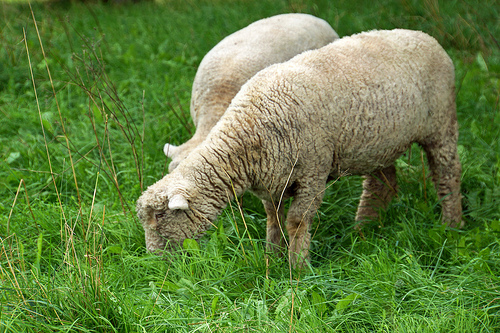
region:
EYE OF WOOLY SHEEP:
[154, 210, 167, 224]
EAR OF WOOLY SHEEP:
[166, 194, 190, 217]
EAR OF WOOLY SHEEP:
[157, 138, 177, 157]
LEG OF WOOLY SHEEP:
[262, 188, 287, 273]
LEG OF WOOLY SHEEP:
[286, 190, 308, 278]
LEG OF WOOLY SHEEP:
[353, 173, 395, 250]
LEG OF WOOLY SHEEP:
[419, 135, 469, 252]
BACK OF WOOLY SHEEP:
[311, 50, 385, 79]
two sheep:
[129, 14, 454, 261]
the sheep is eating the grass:
[141, 232, 168, 261]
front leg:
[279, 222, 315, 277]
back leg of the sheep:
[441, 182, 470, 224]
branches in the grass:
[70, 62, 139, 142]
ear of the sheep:
[168, 197, 188, 214]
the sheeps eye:
[153, 209, 167, 224]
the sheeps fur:
[274, 85, 411, 141]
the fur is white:
[275, 70, 425, 127]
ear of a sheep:
[166, 197, 191, 212]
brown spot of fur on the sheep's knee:
[284, 214, 313, 234]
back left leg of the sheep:
[416, 138, 478, 225]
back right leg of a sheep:
[356, 165, 405, 228]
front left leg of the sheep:
[283, 172, 337, 271]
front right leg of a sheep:
[261, 190, 287, 253]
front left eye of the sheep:
[153, 209, 165, 221]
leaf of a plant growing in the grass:
[183, 238, 200, 257]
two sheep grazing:
[130, 8, 471, 275]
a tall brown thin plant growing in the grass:
[28, 2, 91, 292]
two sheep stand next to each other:
[134, 11, 471, 275]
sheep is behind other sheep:
[160, 12, 343, 185]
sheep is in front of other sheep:
[132, 26, 469, 263]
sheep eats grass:
[162, 9, 344, 177]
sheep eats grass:
[133, 29, 463, 271]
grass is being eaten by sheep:
[1, 2, 498, 328]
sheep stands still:
[132, 28, 469, 270]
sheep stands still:
[162, 11, 340, 166]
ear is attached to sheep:
[165, 191, 188, 211]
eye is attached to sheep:
[153, 207, 168, 222]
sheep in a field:
[61, 53, 499, 273]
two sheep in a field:
[94, 47, 456, 319]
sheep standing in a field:
[173, 11, 478, 330]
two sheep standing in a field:
[124, 44, 424, 303]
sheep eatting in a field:
[133, 3, 403, 320]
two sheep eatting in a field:
[171, 36, 401, 324]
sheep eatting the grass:
[97, 26, 351, 315]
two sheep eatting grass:
[93, 46, 442, 330]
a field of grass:
[33, 58, 261, 311]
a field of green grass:
[89, 168, 401, 325]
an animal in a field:
[137, 78, 340, 240]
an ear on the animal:
[158, 188, 197, 267]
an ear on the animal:
[157, 140, 204, 167]